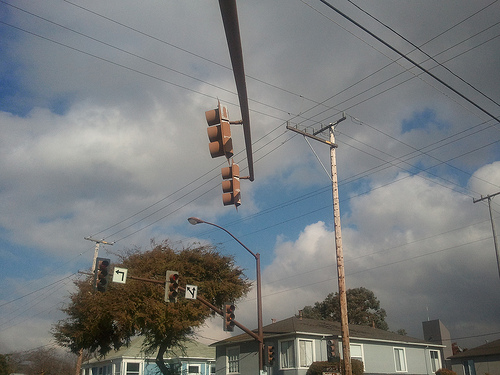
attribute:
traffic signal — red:
[164, 268, 181, 303]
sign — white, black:
[111, 266, 128, 283]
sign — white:
[182, 284, 199, 298]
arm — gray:
[77, 270, 258, 347]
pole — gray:
[256, 252, 266, 374]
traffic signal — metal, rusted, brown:
[204, 99, 234, 157]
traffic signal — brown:
[222, 159, 244, 207]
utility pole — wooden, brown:
[285, 115, 352, 373]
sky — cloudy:
[0, 1, 498, 351]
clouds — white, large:
[191, 162, 499, 349]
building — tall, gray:
[422, 319, 454, 368]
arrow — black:
[115, 270, 126, 281]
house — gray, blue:
[207, 316, 448, 374]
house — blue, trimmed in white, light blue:
[80, 324, 219, 374]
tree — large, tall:
[49, 240, 256, 374]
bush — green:
[307, 359, 364, 374]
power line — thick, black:
[320, 1, 500, 124]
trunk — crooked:
[155, 343, 175, 374]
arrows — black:
[185, 286, 197, 297]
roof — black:
[210, 316, 464, 341]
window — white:
[122, 361, 144, 374]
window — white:
[185, 364, 200, 374]